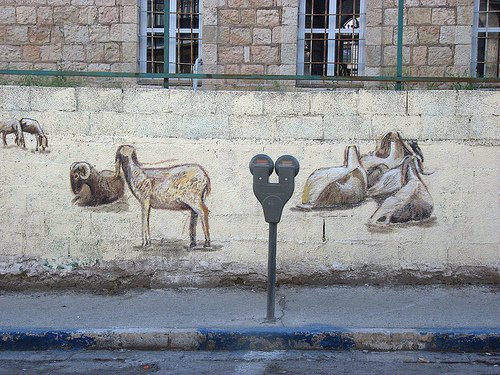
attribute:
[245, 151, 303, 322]
parkingmeter. —  lone, two part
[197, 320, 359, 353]
sidewalk — blue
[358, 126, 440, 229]
wall — red, brick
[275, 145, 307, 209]
parking meter — dual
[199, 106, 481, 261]
wall — brick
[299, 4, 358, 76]
bars — metal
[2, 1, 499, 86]
wall — standard, brick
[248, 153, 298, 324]
parking meter — black, metal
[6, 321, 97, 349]
paint — peeling, blue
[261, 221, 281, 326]
pole — green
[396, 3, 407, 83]
pole — green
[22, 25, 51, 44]
brick — brown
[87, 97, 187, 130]
wall — dingy, beige, brick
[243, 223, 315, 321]
pole — metal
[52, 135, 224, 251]
goats — grazing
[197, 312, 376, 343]
paint — blue, faded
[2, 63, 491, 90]
pole — green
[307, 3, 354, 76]
metal — rusting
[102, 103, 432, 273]
drawings — animal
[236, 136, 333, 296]
meter — parking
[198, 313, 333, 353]
painting — blue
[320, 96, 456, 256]
goats — three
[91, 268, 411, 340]
sidewalk — gray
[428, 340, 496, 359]
paint — blue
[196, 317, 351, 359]
paint — blue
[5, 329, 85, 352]
paint — blue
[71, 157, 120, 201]
buffalo — seated